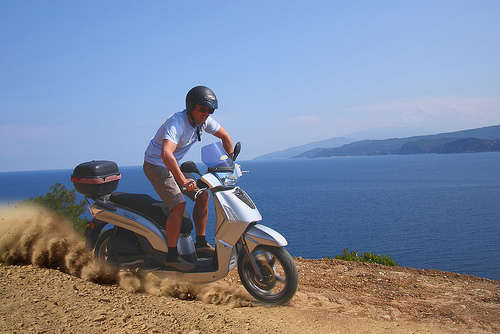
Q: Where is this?
A: This is at the ocean.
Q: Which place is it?
A: It is an ocean.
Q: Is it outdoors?
A: Yes, it is outdoors.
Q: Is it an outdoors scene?
A: Yes, it is outdoors.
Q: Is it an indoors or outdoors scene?
A: It is outdoors.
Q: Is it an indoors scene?
A: No, it is outdoors.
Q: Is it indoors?
A: No, it is outdoors.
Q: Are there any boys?
A: No, there are no boys.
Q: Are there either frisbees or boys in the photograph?
A: No, there are no boys or frisbees.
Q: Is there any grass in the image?
A: Yes, there is grass.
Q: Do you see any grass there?
A: Yes, there is grass.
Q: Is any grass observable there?
A: Yes, there is grass.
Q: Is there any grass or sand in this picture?
A: Yes, there is grass.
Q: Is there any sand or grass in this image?
A: Yes, there is grass.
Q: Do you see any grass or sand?
A: Yes, there is grass.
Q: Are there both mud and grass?
A: No, there is grass but no mud.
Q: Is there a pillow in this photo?
A: No, there are no pillows.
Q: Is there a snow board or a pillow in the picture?
A: No, there are no pillows or snowboards.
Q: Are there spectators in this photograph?
A: No, there are no spectators.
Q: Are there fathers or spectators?
A: No, there are no spectators or fathers.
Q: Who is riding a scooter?
A: The man is riding a scooter.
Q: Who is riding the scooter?
A: The man is riding a scooter.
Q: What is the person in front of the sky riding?
A: The man is riding a scooter.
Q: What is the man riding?
A: The man is riding a scooter.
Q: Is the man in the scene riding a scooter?
A: Yes, the man is riding a scooter.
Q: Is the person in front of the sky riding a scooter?
A: Yes, the man is riding a scooter.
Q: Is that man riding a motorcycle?
A: No, the man is riding a scooter.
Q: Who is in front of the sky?
A: The man is in front of the sky.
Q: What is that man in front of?
A: The man is in front of the sky.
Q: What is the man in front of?
A: The man is in front of the sky.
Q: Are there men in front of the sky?
A: Yes, there is a man in front of the sky.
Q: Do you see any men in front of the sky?
A: Yes, there is a man in front of the sky.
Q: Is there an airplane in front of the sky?
A: No, there is a man in front of the sky.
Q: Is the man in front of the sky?
A: Yes, the man is in front of the sky.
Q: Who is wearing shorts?
A: The man is wearing shorts.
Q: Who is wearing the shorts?
A: The man is wearing shorts.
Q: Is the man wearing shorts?
A: Yes, the man is wearing shorts.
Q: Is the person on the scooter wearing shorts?
A: Yes, the man is wearing shorts.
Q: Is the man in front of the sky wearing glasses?
A: No, the man is wearing shorts.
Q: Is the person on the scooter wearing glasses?
A: No, the man is wearing shorts.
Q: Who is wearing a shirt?
A: The man is wearing a shirt.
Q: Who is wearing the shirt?
A: The man is wearing a shirt.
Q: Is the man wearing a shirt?
A: Yes, the man is wearing a shirt.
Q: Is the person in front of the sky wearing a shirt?
A: Yes, the man is wearing a shirt.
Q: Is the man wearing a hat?
A: No, the man is wearing a shirt.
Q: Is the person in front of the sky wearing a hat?
A: No, the man is wearing a shirt.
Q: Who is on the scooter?
A: The man is on the scooter.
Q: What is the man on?
A: The man is on the scooter.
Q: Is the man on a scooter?
A: Yes, the man is on a scooter.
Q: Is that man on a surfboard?
A: No, the man is on a scooter.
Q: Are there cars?
A: No, there are no cars.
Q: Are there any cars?
A: No, there are no cars.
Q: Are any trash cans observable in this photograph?
A: No, there are no trash cans.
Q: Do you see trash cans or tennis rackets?
A: No, there are no trash cans or tennis rackets.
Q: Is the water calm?
A: Yes, the water is calm.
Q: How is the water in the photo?
A: The water is calm.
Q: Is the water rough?
A: No, the water is calm.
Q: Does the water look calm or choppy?
A: The water is calm.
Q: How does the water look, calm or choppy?
A: The water is calm.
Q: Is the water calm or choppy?
A: The water is calm.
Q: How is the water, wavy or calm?
A: The water is calm.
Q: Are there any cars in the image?
A: No, there are no cars.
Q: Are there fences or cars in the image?
A: No, there are no cars or fences.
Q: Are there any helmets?
A: Yes, there is a helmet.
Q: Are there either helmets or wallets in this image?
A: Yes, there is a helmet.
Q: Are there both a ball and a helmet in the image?
A: No, there is a helmet but no balls.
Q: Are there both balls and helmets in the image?
A: No, there is a helmet but no balls.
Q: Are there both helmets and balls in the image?
A: No, there is a helmet but no balls.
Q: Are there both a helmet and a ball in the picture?
A: No, there is a helmet but no balls.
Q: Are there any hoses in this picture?
A: No, there are no hoses.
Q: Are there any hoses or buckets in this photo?
A: No, there are no hoses or buckets.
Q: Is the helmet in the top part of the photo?
A: Yes, the helmet is in the top of the image.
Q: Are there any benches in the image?
A: No, there are no benches.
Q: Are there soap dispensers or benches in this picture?
A: No, there are no benches or soap dispensers.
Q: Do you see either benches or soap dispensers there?
A: No, there are no benches or soap dispensers.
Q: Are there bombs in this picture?
A: No, there are no bombs.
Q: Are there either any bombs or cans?
A: No, there are no bombs or cans.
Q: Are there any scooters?
A: Yes, there is a scooter.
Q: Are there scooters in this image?
A: Yes, there is a scooter.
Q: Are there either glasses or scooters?
A: Yes, there is a scooter.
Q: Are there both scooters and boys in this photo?
A: No, there is a scooter but no boys.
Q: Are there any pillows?
A: No, there are no pillows.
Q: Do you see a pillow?
A: No, there are no pillows.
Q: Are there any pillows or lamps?
A: No, there are no pillows or lamps.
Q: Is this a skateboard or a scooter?
A: This is a scooter.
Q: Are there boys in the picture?
A: No, there are no boys.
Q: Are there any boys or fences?
A: No, there are no boys or fences.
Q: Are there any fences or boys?
A: No, there are no boys or fences.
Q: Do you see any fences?
A: No, there are no fences.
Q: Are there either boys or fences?
A: No, there are no fences or boys.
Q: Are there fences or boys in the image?
A: No, there are no fences or boys.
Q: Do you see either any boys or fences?
A: No, there are no fences or boys.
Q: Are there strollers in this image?
A: No, there are no strollers.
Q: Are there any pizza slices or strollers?
A: No, there are no strollers or pizza slices.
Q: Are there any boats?
A: No, there are no boats.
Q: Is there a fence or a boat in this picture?
A: No, there are no boats or fences.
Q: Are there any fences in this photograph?
A: No, there are no fences.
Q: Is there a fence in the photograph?
A: No, there are no fences.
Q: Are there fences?
A: No, there are no fences.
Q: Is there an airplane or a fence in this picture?
A: No, there are no fences or airplanes.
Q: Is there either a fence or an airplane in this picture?
A: No, there are no fences or airplanes.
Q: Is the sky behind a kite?
A: No, the sky is behind a man.